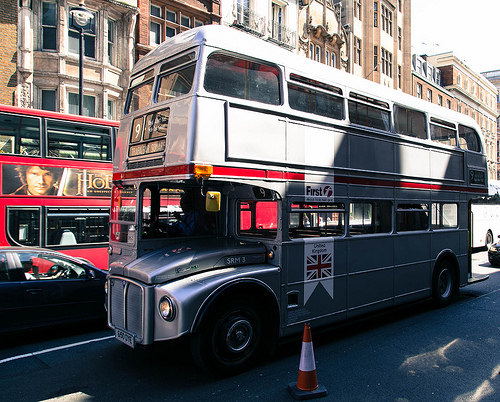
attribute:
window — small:
[455, 117, 486, 154]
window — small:
[390, 97, 431, 142]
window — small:
[282, 67, 346, 128]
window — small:
[44, 115, 112, 163]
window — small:
[291, 85, 346, 119]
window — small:
[345, 98, 391, 130]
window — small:
[291, 212, 341, 232]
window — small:
[395, 208, 432, 231]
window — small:
[460, 126, 480, 150]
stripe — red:
[111, 157, 498, 194]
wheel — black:
[191, 282, 282, 372]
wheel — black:
[426, 243, 470, 308]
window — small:
[350, 91, 399, 136]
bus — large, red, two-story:
[2, 92, 114, 321]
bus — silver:
[83, 34, 483, 359]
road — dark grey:
[0, 253, 499, 398]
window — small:
[328, 171, 418, 282]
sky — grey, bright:
[407, 5, 497, 77]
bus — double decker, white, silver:
[27, 21, 478, 367]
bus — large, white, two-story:
[103, 22, 492, 380]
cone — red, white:
[286, 320, 335, 399]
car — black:
[0, 239, 102, 329]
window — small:
[393, 106, 427, 141]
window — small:
[427, 117, 457, 150]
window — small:
[394, 202, 428, 234]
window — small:
[202, 47, 282, 107]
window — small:
[285, 70, 345, 121]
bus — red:
[0, 100, 326, 295]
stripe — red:
[107, 162, 484, 189]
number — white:
[224, 251, 250, 269]